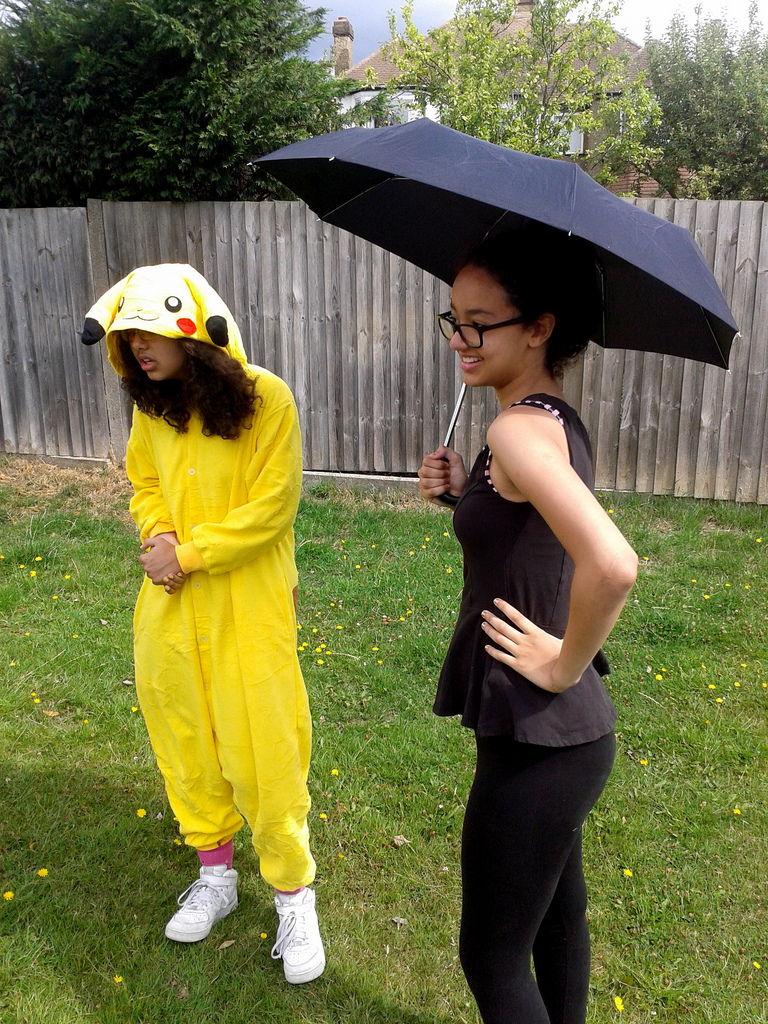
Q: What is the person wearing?
A: Pikachu pajamas.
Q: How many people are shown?
A: Two.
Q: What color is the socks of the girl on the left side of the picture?
A: Pink.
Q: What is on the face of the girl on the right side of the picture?
A: Eyeglasses.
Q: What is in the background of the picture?
A: A fence.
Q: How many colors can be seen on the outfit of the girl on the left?
A: 5.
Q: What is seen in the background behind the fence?
A: A house and trees.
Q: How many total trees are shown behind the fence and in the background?
A: Three.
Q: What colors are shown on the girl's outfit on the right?
A: Black and white.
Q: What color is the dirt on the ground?
A: Brown.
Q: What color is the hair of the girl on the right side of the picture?
A: Black.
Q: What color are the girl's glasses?
A: Black.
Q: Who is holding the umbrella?
A: The girl in black.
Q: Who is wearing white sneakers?
A: The girl in the Pikachu hoodie.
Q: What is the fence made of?
A: Wood.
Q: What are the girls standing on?
A: Grass.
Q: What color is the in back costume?
A: Yellow.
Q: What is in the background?
A: Trees and a house.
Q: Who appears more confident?
A: The woman with the glasses.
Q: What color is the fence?
A: Gray.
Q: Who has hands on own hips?
A: The woman in front.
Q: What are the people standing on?
A: The grass.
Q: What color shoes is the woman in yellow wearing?
A: White.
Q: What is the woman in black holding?
A: An umbrella.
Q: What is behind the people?
A: A fence.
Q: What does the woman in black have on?
A: Glasses.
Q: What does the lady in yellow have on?
A: A costume.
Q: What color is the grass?
A: Green.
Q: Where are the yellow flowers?
A: In the grass.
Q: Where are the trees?
A: Behind the fence.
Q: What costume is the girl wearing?
A: Pikachu.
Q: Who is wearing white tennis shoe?
A: Young girl.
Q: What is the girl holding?
A: Umbrella.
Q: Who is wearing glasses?
A: A young girl.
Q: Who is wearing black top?
A: Girl to right.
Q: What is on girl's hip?
A: Her hand.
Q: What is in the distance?
A: A house.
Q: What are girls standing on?
A: Grass.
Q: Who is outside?
A: 2 girls.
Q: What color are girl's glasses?
A: Black.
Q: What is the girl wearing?
A: A pokemon costume.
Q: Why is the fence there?
A: It is divides two yards.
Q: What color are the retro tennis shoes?
A: They are white.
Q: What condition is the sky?
A: Clear and blue.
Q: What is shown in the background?
A: The house next door.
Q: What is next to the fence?
A: A small area of dead grass.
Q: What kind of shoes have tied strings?
A: Athletic shoes.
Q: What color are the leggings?
A: They are black.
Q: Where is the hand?
A: On the hip.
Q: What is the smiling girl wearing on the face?
A: Glasses.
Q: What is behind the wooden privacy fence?
A: House.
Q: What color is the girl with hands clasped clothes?
A: Yellow.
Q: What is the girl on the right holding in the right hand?
A: Umbrella.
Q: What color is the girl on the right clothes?
A: Black.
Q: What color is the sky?
A: Gray.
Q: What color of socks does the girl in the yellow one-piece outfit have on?
A: Pink.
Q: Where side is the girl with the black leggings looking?
A: Left.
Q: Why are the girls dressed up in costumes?
A: Party.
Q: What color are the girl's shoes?
A: White.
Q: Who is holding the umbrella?
A: Girl on the right.